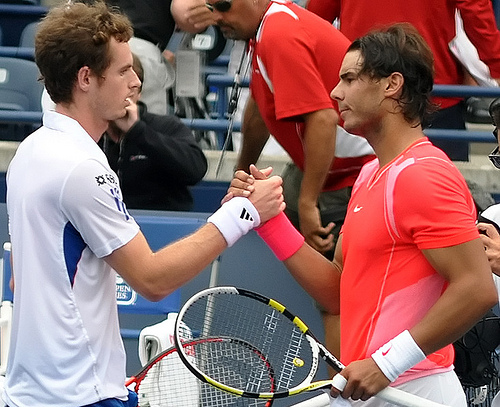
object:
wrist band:
[207, 196, 260, 248]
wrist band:
[371, 328, 426, 383]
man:
[219, 22, 499, 406]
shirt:
[337, 136, 481, 390]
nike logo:
[353, 204, 363, 212]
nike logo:
[381, 343, 391, 356]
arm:
[60, 158, 246, 303]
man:
[4, 0, 291, 406]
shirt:
[4, 109, 141, 407]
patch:
[64, 221, 88, 291]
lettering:
[94, 174, 118, 187]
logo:
[239, 207, 255, 222]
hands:
[240, 167, 289, 230]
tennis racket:
[174, 285, 451, 406]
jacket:
[97, 101, 208, 212]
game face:
[330, 48, 387, 135]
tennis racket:
[125, 335, 276, 406]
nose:
[330, 80, 347, 100]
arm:
[370, 164, 499, 382]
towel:
[139, 312, 200, 406]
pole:
[0, 109, 497, 142]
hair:
[34, 0, 133, 109]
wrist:
[205, 195, 260, 248]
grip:
[372, 384, 450, 406]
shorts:
[81, 388, 136, 406]